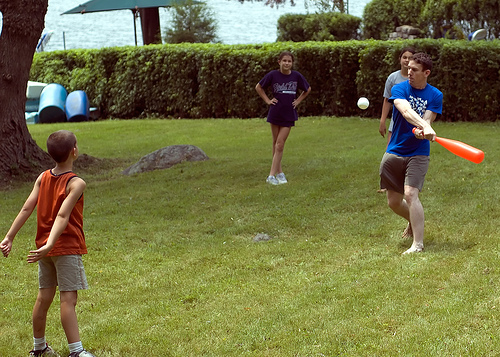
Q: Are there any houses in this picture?
A: No, there are no houses.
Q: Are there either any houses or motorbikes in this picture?
A: No, there are no houses or motorbikes.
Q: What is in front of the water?
A: The hedge is in front of the water.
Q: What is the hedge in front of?
A: The hedge is in front of the water.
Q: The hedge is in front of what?
A: The hedge is in front of the water.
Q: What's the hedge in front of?
A: The hedge is in front of the water.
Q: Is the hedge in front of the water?
A: Yes, the hedge is in front of the water.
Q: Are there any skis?
A: No, there are no skis.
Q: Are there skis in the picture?
A: No, there are no skis.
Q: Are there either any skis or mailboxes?
A: No, there are no skis or mailboxes.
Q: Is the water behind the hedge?
A: Yes, the water is behind the hedge.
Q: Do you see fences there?
A: No, there are no fences.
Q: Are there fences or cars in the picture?
A: No, there are no fences or cars.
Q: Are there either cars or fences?
A: No, there are no fences or cars.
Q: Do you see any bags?
A: No, there are no bags.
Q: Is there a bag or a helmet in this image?
A: No, there are no bags or helmets.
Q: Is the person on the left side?
A: Yes, the person is on the left of the image.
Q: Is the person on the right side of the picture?
A: No, the person is on the left of the image.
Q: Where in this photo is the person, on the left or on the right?
A: The person is on the left of the image.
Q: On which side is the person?
A: The person is on the left of the image.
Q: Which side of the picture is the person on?
A: The person is on the left of the image.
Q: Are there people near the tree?
A: Yes, there is a person near the tree.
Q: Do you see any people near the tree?
A: Yes, there is a person near the tree.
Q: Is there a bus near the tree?
A: No, there is a person near the tree.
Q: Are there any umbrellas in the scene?
A: Yes, there is an umbrella.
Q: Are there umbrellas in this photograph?
A: Yes, there is an umbrella.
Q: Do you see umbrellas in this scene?
A: Yes, there is an umbrella.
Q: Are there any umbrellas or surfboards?
A: Yes, there is an umbrella.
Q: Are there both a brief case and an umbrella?
A: No, there is an umbrella but no briefcases.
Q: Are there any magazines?
A: No, there are no magazines.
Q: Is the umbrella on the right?
A: No, the umbrella is on the left of the image.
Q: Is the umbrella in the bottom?
A: No, the umbrella is in the top of the image.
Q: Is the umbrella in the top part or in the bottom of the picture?
A: The umbrella is in the top of the image.